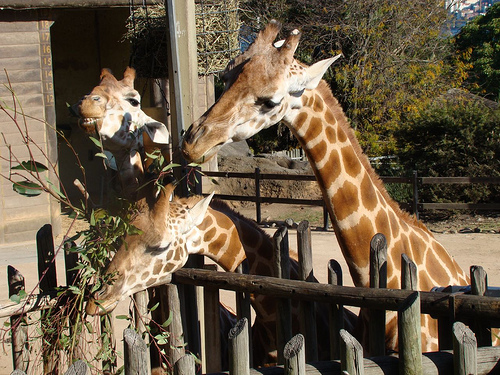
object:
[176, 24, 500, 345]
giraffe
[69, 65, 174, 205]
giraffe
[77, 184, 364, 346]
giraffe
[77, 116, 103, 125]
teeth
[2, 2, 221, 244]
building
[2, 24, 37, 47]
siding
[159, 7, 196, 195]
frame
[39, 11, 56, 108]
numbers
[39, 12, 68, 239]
frame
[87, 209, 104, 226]
leaves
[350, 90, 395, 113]
leaves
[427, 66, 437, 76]
yellow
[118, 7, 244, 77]
hay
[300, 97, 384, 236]
spots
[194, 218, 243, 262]
spots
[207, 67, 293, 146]
face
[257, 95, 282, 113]
eye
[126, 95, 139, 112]
eye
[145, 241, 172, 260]
eye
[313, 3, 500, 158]
trees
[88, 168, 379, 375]
giraffes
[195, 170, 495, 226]
fence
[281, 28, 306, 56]
horn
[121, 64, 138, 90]
horn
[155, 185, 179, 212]
horn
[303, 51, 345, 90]
ear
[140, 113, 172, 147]
ear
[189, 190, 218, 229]
ear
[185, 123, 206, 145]
nose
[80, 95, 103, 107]
nose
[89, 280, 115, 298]
nose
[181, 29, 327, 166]
head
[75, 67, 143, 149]
head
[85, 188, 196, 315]
head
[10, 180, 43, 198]
leaf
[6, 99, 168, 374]
tree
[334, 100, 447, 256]
back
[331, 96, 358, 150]
comb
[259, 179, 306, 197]
dirt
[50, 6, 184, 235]
door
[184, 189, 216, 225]
ears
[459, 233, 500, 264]
ground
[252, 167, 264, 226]
posts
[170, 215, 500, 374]
corral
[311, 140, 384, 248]
design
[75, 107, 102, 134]
mouth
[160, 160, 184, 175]
grass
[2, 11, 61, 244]
wall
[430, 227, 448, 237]
rocks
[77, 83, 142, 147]
face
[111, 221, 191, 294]
face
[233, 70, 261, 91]
light